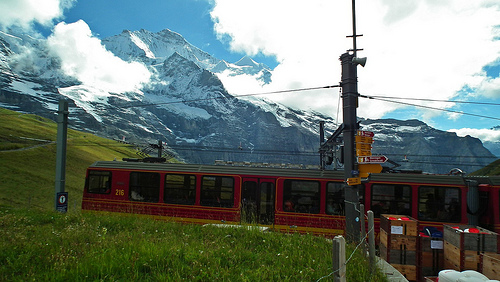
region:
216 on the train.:
[103, 180, 135, 205]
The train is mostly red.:
[86, 154, 498, 238]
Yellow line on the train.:
[118, 209, 343, 241]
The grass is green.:
[8, 141, 51, 203]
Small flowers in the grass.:
[190, 226, 325, 279]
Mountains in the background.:
[13, 31, 498, 186]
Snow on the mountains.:
[120, 27, 209, 110]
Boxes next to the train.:
[383, 220, 498, 276]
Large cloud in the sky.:
[271, 4, 435, 87]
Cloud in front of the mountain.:
[56, 15, 148, 100]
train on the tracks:
[77, 146, 499, 250]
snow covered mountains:
[12, 7, 326, 157]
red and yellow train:
[73, 160, 499, 252]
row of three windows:
[129, 169, 235, 207]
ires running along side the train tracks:
[75, 129, 320, 169]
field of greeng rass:
[7, 207, 358, 279]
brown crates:
[368, 207, 498, 279]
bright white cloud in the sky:
[193, 5, 480, 115]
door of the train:
[237, 179, 279, 235]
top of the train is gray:
[94, 154, 322, 181]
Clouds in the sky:
[19, 7, 474, 144]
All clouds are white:
[24, 9, 445, 147]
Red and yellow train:
[67, 124, 426, 258]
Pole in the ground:
[296, 7, 386, 252]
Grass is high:
[23, 220, 305, 280]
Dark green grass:
[31, 185, 310, 273]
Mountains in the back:
[23, 8, 467, 179]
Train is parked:
[61, 113, 497, 242]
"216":
[110, 177, 130, 208]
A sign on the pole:
[53, 182, 80, 213]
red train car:
[79, 160, 496, 235]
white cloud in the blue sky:
[1, 3, 65, 32]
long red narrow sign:
[356, 152, 388, 164]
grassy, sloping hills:
[2, 106, 379, 276]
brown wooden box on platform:
[441, 223, 481, 269]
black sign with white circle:
[57, 190, 67, 212]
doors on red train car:
[241, 176, 275, 223]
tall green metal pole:
[54, 98, 66, 208]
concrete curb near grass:
[324, 235, 406, 280]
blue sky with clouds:
[3, 0, 499, 129]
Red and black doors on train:
[241, 176, 276, 225]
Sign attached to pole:
[56, 193, 68, 211]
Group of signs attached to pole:
[354, 131, 386, 174]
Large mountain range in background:
[4, 23, 218, 121]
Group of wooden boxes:
[377, 214, 417, 265]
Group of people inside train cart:
[422, 191, 459, 223]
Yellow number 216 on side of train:
[113, 186, 125, 198]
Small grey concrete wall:
[380, 260, 405, 279]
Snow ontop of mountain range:
[148, 91, 210, 123]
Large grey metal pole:
[54, 96, 66, 193]